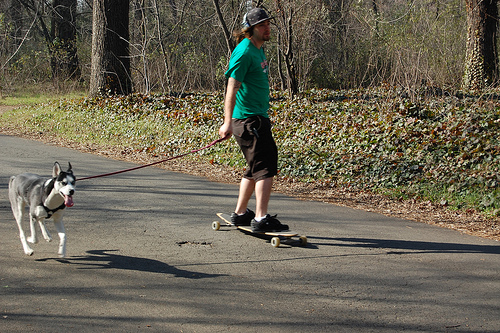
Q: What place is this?
A: It is a street.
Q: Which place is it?
A: It is a street.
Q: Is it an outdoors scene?
A: Yes, it is outdoors.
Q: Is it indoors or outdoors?
A: It is outdoors.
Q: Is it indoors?
A: No, it is outdoors.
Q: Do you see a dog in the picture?
A: Yes, there is a dog.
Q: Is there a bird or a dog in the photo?
A: Yes, there is a dog.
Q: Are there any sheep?
A: No, there are no sheep.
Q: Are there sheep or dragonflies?
A: No, there are no sheep or dragonflies.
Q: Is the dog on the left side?
A: Yes, the dog is on the left of the image.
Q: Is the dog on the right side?
A: No, the dog is on the left of the image.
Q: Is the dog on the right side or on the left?
A: The dog is on the left of the image.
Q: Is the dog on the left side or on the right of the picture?
A: The dog is on the left of the image.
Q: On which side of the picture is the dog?
A: The dog is on the left of the image.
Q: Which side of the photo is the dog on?
A: The dog is on the left of the image.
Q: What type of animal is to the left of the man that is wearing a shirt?
A: The animal is a dog.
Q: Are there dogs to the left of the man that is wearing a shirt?
A: Yes, there is a dog to the left of the man.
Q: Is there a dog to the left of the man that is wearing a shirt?
A: Yes, there is a dog to the left of the man.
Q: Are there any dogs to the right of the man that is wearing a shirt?
A: No, the dog is to the left of the man.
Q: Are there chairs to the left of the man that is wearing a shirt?
A: No, there is a dog to the left of the man.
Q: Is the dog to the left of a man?
A: Yes, the dog is to the left of a man.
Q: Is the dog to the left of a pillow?
A: No, the dog is to the left of a man.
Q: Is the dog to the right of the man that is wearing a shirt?
A: No, the dog is to the left of the man.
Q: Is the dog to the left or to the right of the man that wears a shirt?
A: The dog is to the left of the man.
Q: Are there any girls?
A: No, there are no girls.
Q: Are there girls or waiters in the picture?
A: No, there are no girls or waiters.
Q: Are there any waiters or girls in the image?
A: No, there are no girls or waiters.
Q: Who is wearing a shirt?
A: The man is wearing a shirt.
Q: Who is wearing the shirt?
A: The man is wearing a shirt.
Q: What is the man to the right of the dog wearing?
A: The man is wearing a shirt.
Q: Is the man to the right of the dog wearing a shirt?
A: Yes, the man is wearing a shirt.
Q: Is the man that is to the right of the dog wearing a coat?
A: No, the man is wearing a shirt.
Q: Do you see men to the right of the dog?
A: Yes, there is a man to the right of the dog.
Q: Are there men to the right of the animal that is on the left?
A: Yes, there is a man to the right of the dog.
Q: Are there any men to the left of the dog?
A: No, the man is to the right of the dog.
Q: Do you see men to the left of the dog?
A: No, the man is to the right of the dog.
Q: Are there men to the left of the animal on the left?
A: No, the man is to the right of the dog.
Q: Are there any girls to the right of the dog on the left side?
A: No, there is a man to the right of the dog.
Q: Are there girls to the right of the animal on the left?
A: No, there is a man to the right of the dog.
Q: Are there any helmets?
A: No, there are no helmets.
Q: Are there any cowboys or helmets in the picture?
A: No, there are no helmets or cowboys.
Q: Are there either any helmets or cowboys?
A: No, there are no helmets or cowboys.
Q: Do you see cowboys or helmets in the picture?
A: No, there are no helmets or cowboys.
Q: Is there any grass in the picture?
A: Yes, there is grass.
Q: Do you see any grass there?
A: Yes, there is grass.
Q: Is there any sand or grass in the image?
A: Yes, there is grass.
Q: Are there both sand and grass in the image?
A: No, there is grass but no sand.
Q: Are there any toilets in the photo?
A: No, there are no toilets.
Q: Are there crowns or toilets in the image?
A: No, there are no toilets or crowns.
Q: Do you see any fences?
A: No, there are no fences.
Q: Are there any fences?
A: No, there are no fences.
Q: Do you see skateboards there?
A: Yes, there is a skateboard.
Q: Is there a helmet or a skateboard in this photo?
A: Yes, there is a skateboard.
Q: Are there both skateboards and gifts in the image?
A: No, there is a skateboard but no gifts.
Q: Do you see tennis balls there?
A: No, there are no tennis balls.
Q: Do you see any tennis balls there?
A: No, there are no tennis balls.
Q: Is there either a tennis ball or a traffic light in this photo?
A: No, there are no tennis balls or traffic lights.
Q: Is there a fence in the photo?
A: No, there are no fences.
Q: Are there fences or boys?
A: No, there are no fences or boys.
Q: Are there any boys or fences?
A: No, there are no fences or boys.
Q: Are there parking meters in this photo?
A: No, there are no parking meters.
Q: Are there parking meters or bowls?
A: No, there are no parking meters or bowls.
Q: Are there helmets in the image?
A: No, there are no helmets.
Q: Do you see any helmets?
A: No, there are no helmets.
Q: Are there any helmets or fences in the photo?
A: No, there are no helmets or fences.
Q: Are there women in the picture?
A: No, there are no women.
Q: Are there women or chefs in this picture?
A: No, there are no women or chefs.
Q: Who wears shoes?
A: The man wears shoes.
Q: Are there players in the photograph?
A: No, there are no players.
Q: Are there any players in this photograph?
A: No, there are no players.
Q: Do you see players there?
A: No, there are no players.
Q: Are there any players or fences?
A: No, there are no players or fences.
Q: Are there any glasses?
A: No, there are no glasses.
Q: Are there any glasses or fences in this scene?
A: No, there are no glasses or fences.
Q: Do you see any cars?
A: No, there are no cars.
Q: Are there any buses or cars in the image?
A: No, there are no cars or buses.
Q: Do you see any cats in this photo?
A: No, there are no cats.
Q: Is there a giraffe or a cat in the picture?
A: No, there are no cats or giraffes.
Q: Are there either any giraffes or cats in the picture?
A: No, there are no cats or giraffes.